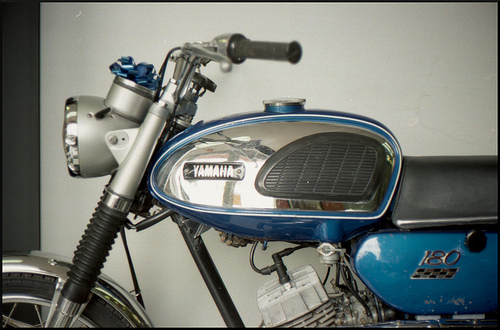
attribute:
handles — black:
[190, 25, 311, 76]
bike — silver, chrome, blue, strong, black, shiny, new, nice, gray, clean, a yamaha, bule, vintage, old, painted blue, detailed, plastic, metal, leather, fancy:
[4, 31, 493, 329]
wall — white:
[41, 5, 498, 85]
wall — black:
[0, 7, 41, 302]